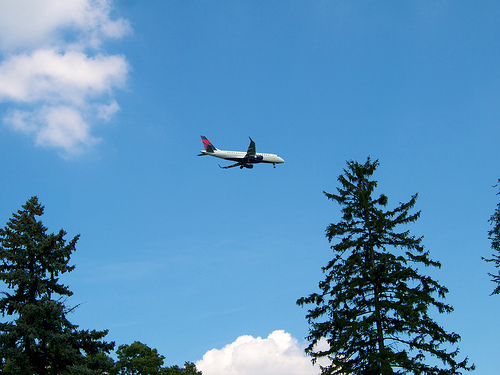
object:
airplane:
[196, 136, 285, 173]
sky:
[1, 2, 498, 124]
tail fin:
[205, 144, 214, 152]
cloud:
[193, 327, 349, 374]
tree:
[294, 157, 477, 373]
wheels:
[239, 166, 243, 170]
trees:
[0, 194, 188, 375]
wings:
[245, 136, 256, 157]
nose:
[273, 155, 285, 165]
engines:
[244, 154, 264, 162]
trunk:
[357, 192, 391, 373]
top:
[325, 157, 419, 227]